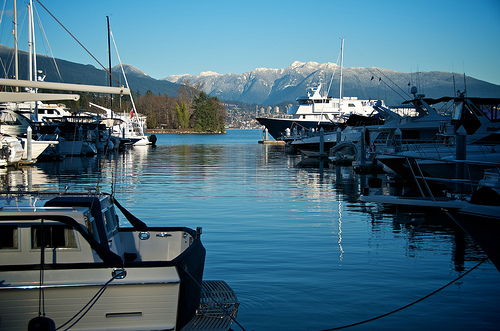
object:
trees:
[185, 98, 226, 133]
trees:
[171, 102, 190, 132]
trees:
[196, 89, 209, 111]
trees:
[141, 89, 163, 132]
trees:
[162, 91, 174, 129]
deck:
[182, 279, 240, 330]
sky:
[0, 0, 500, 87]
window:
[319, 97, 329, 102]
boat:
[0, 187, 241, 330]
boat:
[251, 38, 419, 140]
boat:
[359, 167, 500, 273]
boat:
[107, 13, 157, 146]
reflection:
[284, 160, 339, 213]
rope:
[183, 262, 246, 329]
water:
[1, 127, 500, 330]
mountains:
[161, 60, 499, 111]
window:
[33, 227, 71, 248]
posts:
[317, 126, 327, 171]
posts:
[333, 128, 342, 157]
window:
[0, 226, 23, 249]